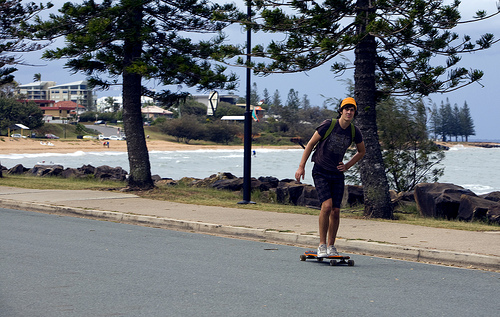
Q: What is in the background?
A: Water.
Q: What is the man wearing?
A: Hat.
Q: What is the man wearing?
A: Shirt.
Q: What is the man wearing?
A: Shoes.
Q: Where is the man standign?
A: Skateboard.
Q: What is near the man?
A: Shorelines.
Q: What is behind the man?
A: Trees.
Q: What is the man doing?
A: Skating.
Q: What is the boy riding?
A: A skateboard.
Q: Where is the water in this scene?
A: To the left of the boy.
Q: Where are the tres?
A: Behind the boy.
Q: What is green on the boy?
A: Backpack straps.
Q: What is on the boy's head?
A: A hat.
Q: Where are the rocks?
A: Near the trees.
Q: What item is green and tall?
A: A tree.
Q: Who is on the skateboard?
A: A rider.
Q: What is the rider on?
A: A skateboard.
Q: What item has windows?
A: A house.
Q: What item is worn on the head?
A: A hat.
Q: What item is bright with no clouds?
A: A sky.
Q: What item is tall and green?
A: A tree.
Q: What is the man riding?
A: A skateboard.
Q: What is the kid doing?
A: Skateboarding.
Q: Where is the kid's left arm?
A: On his side.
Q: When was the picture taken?
A: During the day.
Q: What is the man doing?
A: Skating.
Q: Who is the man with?
A: No one.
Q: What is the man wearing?
A: Sneakers.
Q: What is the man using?
A: Skates.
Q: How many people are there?
A: 1.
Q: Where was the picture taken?
A: By the beach.